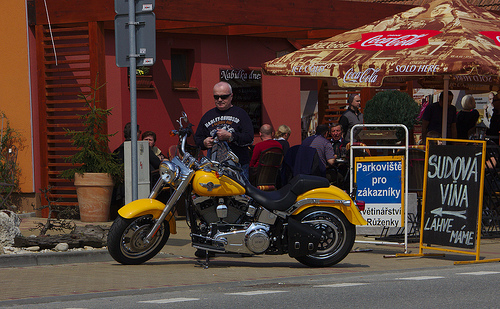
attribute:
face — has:
[211, 82, 233, 114]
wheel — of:
[105, 199, 177, 267]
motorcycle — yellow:
[104, 119, 386, 290]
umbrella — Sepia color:
[257, 3, 497, 123]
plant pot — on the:
[73, 171, 115, 223]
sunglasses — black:
[213, 90, 230, 100]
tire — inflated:
[289, 202, 356, 268]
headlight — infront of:
[152, 159, 177, 190]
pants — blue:
[188, 149, 253, 265]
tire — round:
[102, 193, 177, 267]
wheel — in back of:
[288, 191, 356, 264]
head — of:
[211, 82, 233, 109]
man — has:
[193, 81, 252, 255]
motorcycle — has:
[109, 154, 414, 269]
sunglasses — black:
[210, 91, 231, 101]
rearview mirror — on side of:
[214, 147, 241, 164]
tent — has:
[262, 3, 498, 89]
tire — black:
[106, 208, 168, 266]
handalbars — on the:
[172, 115, 252, 168]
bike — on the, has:
[110, 114, 360, 272]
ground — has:
[42, 219, 105, 239]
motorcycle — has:
[108, 115, 366, 278]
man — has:
[192, 79, 246, 163]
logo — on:
[359, 34, 429, 58]